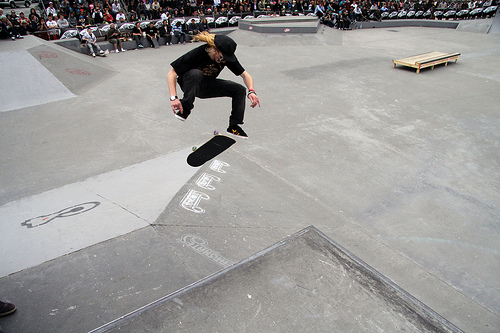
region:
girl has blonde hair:
[192, 15, 218, 53]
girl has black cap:
[218, 32, 240, 53]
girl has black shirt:
[169, 36, 232, 79]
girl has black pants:
[167, 77, 248, 127]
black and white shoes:
[220, 128, 247, 151]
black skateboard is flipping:
[185, 128, 235, 183]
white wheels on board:
[177, 124, 221, 181]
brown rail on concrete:
[399, 44, 452, 74]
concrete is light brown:
[367, 100, 441, 225]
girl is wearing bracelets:
[230, 58, 272, 98]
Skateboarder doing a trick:
[167, 31, 261, 167]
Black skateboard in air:
[187, 131, 234, 168]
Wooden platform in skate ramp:
[395, 49, 460, 74]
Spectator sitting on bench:
[75, 22, 109, 58]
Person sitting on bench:
[105, 23, 127, 54]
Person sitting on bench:
[128, 21, 148, 48]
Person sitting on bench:
[143, 21, 161, 48]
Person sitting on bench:
[159, 18, 175, 47]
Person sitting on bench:
[170, 19, 188, 46]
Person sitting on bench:
[188, 17, 196, 38]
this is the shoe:
[227, 122, 245, 137]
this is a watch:
[169, 93, 178, 100]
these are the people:
[27, 2, 191, 33]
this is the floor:
[295, 152, 477, 222]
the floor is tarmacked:
[252, 143, 391, 235]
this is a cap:
[216, 39, 232, 48]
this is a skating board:
[194, 140, 229, 160]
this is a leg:
[220, 80, 248, 135]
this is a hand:
[167, 70, 181, 109]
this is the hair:
[201, 32, 213, 42]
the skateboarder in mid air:
[167, 29, 261, 138]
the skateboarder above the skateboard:
[166, 30, 262, 139]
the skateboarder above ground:
[167, 30, 260, 139]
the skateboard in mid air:
[185, 130, 235, 166]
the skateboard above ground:
[186, 130, 235, 167]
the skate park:
[1, 14, 498, 331]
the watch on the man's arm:
[169, 95, 177, 101]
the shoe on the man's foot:
[225, 123, 248, 138]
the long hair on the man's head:
[190, 30, 216, 50]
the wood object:
[392, 50, 459, 74]